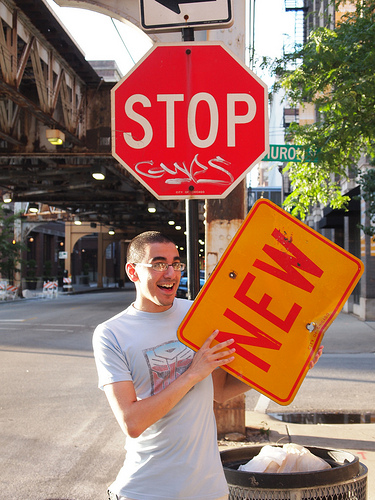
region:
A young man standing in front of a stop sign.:
[90, 228, 324, 499]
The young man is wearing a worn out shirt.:
[91, 295, 229, 497]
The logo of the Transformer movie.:
[141, 338, 194, 396]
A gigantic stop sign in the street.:
[109, 40, 271, 202]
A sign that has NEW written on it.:
[174, 195, 365, 408]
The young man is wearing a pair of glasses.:
[126, 260, 184, 272]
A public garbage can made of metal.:
[212, 439, 370, 497]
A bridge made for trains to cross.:
[0, 0, 204, 261]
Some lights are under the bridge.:
[44, 129, 204, 246]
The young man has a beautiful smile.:
[154, 278, 178, 293]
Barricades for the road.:
[0, 277, 61, 304]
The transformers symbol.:
[136, 336, 190, 398]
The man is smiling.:
[113, 220, 190, 313]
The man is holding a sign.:
[90, 197, 370, 438]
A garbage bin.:
[216, 438, 366, 494]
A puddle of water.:
[262, 398, 369, 428]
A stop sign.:
[98, 33, 271, 201]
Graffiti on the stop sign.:
[130, 152, 235, 193]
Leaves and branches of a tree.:
[271, 23, 370, 208]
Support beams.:
[54, 228, 126, 290]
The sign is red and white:
[99, 58, 273, 202]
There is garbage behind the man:
[212, 424, 371, 482]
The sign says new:
[204, 229, 357, 402]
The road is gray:
[15, 396, 117, 491]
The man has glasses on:
[145, 242, 198, 306]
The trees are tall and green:
[261, 29, 374, 143]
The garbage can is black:
[231, 430, 334, 495]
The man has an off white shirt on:
[127, 357, 211, 483]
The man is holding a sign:
[99, 238, 276, 394]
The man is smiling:
[149, 265, 194, 310]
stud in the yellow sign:
[225, 257, 240, 281]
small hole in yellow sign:
[214, 266, 244, 290]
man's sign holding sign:
[194, 318, 262, 385]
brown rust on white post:
[196, 198, 232, 242]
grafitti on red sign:
[119, 139, 244, 207]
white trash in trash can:
[233, 434, 332, 483]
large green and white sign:
[246, 135, 327, 162]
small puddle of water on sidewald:
[269, 408, 366, 429]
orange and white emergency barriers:
[39, 273, 68, 294]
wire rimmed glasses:
[128, 252, 201, 277]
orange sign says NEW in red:
[169, 211, 371, 402]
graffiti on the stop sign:
[122, 151, 255, 202]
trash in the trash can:
[250, 435, 331, 475]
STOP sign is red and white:
[114, 39, 291, 198]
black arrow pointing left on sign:
[138, 1, 243, 18]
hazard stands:
[5, 271, 80, 311]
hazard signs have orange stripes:
[6, 282, 64, 304]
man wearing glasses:
[118, 234, 211, 285]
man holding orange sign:
[104, 232, 346, 418]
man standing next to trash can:
[169, 413, 373, 498]